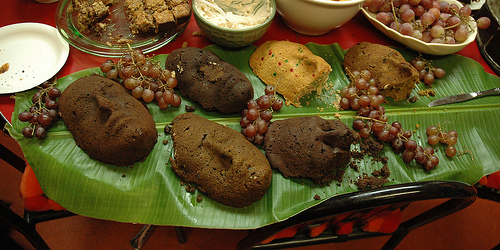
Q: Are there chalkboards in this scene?
A: No, there are no chalkboards.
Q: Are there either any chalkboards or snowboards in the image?
A: No, there are no chalkboards or snowboards.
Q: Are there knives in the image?
A: Yes, there is a knife.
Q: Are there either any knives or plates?
A: Yes, there is a knife.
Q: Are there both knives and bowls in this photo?
A: Yes, there are both a knife and a bowl.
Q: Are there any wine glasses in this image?
A: No, there are no wine glasses.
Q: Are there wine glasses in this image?
A: No, there are no wine glasses.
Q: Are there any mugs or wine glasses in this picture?
A: No, there are no wine glasses or mugs.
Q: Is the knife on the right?
A: Yes, the knife is on the right of the image.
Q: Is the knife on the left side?
A: No, the knife is on the right of the image.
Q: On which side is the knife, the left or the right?
A: The knife is on the right of the image.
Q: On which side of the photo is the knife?
A: The knife is on the right of the image.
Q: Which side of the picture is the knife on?
A: The knife is on the right of the image.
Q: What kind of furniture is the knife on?
A: The knife is on the table.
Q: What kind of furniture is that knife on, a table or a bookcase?
A: The knife is on a table.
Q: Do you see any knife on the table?
A: Yes, there is a knife on the table.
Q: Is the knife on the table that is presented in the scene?
A: Yes, the knife is on the table.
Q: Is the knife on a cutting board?
A: No, the knife is on the table.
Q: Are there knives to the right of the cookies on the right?
A: Yes, there is a knife to the right of the cookies.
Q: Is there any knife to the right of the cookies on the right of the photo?
A: Yes, there is a knife to the right of the cookies.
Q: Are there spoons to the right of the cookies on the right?
A: No, there is a knife to the right of the cookies.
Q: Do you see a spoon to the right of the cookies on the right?
A: No, there is a knife to the right of the cookies.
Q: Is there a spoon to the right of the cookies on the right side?
A: No, there is a knife to the right of the cookies.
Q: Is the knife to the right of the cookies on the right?
A: Yes, the knife is to the right of the cookies.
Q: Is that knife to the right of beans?
A: No, the knife is to the right of the cookies.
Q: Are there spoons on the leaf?
A: No, there is a knife on the leaf.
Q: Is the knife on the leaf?
A: Yes, the knife is on the leaf.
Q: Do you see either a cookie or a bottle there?
A: Yes, there are cookies.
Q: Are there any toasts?
A: No, there are no toasts.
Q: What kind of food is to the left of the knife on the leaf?
A: The food is cookies.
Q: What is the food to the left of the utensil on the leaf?
A: The food is cookies.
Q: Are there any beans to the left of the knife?
A: No, there are cookies to the left of the knife.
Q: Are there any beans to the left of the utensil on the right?
A: No, there are cookies to the left of the knife.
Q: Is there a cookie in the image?
A: Yes, there are cookies.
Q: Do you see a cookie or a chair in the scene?
A: Yes, there are cookies.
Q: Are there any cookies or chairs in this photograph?
A: Yes, there are cookies.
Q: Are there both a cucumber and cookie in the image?
A: No, there are cookies but no cucumbers.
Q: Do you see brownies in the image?
A: Yes, there are brownies.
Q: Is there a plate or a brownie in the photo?
A: Yes, there are brownies.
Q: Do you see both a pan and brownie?
A: No, there are brownies but no pans.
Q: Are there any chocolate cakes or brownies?
A: Yes, there are chocolate brownies.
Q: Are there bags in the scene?
A: No, there are no bags.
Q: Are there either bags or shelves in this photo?
A: No, there are no bags or shelves.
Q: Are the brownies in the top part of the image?
A: Yes, the brownies are in the top of the image.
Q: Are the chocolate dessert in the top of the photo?
A: Yes, the brownies are in the top of the image.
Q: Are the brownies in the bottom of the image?
A: No, the brownies are in the top of the image.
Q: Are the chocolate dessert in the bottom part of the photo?
A: No, the brownies are in the top of the image.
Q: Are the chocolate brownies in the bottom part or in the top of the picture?
A: The brownies are in the top of the image.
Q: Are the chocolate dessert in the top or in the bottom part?
A: The brownies are in the top of the image.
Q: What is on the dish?
A: The brownies are on the dish.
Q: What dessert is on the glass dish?
A: The dessert is brownies.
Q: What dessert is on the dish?
A: The dessert is brownies.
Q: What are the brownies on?
A: The brownies are on the dish.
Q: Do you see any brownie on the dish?
A: Yes, there are brownies on the dish.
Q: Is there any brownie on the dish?
A: Yes, there are brownies on the dish.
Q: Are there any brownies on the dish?
A: Yes, there are brownies on the dish.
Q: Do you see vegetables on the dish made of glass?
A: No, there are brownies on the dish.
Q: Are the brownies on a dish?
A: Yes, the brownies are on a dish.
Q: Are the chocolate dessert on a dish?
A: Yes, the brownies are on a dish.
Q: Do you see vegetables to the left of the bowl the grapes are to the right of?
A: No, there are brownies to the left of the bowl.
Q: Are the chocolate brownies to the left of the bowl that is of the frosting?
A: Yes, the brownies are to the left of the bowl.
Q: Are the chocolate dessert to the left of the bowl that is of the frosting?
A: Yes, the brownies are to the left of the bowl.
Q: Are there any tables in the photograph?
A: Yes, there is a table.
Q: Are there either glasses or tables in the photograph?
A: Yes, there is a table.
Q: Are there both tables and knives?
A: Yes, there are both a table and a knife.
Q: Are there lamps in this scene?
A: No, there are no lamps.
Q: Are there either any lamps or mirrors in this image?
A: No, there are no lamps or mirrors.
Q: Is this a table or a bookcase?
A: This is a table.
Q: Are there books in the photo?
A: No, there are no books.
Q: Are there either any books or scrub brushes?
A: No, there are no books or scrub brushes.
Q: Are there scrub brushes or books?
A: No, there are no books or scrub brushes.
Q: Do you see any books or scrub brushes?
A: No, there are no books or scrub brushes.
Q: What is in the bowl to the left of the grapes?
A: The frosting is in the bowl.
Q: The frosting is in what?
A: The frosting is in the bowl.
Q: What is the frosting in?
A: The frosting is in the bowl.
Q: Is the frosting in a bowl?
A: Yes, the frosting is in a bowl.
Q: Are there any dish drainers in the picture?
A: No, there are no dish drainers.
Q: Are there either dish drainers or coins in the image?
A: No, there are no dish drainers or coins.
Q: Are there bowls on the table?
A: Yes, there is a bowl on the table.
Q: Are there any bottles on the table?
A: No, there is a bowl on the table.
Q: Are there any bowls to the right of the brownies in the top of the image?
A: Yes, there is a bowl to the right of the brownies.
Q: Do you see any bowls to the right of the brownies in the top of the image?
A: Yes, there is a bowl to the right of the brownies.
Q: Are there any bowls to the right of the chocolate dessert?
A: Yes, there is a bowl to the right of the brownies.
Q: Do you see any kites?
A: No, there are no kites.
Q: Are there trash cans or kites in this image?
A: No, there are no kites or trash cans.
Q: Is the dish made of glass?
A: Yes, the dish is made of glass.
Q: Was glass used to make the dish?
A: Yes, the dish is made of glass.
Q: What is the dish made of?
A: The dish is made of glass.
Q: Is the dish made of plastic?
A: No, the dish is made of glass.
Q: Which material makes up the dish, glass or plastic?
A: The dish is made of glass.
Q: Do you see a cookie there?
A: Yes, there are cookies.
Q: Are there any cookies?
A: Yes, there are cookies.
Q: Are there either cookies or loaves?
A: Yes, there are cookies.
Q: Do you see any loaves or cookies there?
A: Yes, there are cookies.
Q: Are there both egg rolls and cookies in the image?
A: No, there are cookies but no egg rolls.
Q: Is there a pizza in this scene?
A: No, there are no pizzas.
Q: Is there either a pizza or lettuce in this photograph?
A: No, there are no pizzas or lettuce.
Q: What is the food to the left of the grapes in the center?
A: The food is cookies.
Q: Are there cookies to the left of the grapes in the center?
A: Yes, there are cookies to the left of the grapes.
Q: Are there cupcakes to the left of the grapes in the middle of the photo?
A: No, there are cookies to the left of the grapes.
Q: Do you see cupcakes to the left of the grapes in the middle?
A: No, there are cookies to the left of the grapes.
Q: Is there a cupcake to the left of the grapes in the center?
A: No, there are cookies to the left of the grapes.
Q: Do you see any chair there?
A: Yes, there is a chair.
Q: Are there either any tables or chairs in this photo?
A: Yes, there is a chair.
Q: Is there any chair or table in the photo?
A: Yes, there is a chair.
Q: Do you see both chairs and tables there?
A: Yes, there are both a chair and a table.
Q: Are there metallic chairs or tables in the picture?
A: Yes, there is a metal chair.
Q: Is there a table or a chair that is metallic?
A: Yes, the chair is metallic.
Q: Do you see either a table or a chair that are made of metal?
A: Yes, the chair is made of metal.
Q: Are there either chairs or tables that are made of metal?
A: Yes, the chair is made of metal.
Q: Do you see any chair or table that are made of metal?
A: Yes, the chair is made of metal.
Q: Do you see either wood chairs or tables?
A: Yes, there is a wood chair.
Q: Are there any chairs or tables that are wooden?
A: Yes, the chair is wooden.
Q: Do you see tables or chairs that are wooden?
A: Yes, the chair is wooden.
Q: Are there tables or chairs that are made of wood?
A: Yes, the chair is made of wood.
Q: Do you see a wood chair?
A: Yes, there is a wood chair.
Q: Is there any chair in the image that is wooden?
A: Yes, there is a wood chair.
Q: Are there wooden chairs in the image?
A: Yes, there is a wood chair.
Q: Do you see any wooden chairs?
A: Yes, there is a wood chair.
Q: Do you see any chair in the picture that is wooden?
A: Yes, there is a chair that is wooden.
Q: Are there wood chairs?
A: Yes, there is a chair that is made of wood.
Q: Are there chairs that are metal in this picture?
A: Yes, there is a metal chair.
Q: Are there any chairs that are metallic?
A: Yes, there is a chair that is metallic.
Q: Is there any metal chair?
A: Yes, there is a chair that is made of metal.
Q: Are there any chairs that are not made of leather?
A: Yes, there is a chair that is made of metal.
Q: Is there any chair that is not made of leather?
A: Yes, there is a chair that is made of metal.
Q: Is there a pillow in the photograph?
A: No, there are no pillows.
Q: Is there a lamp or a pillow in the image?
A: No, there are no pillows or lamps.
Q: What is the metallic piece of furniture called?
A: The piece of furniture is a chair.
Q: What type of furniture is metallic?
A: The furniture is a chair.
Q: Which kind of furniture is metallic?
A: The furniture is a chair.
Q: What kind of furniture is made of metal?
A: The furniture is a chair.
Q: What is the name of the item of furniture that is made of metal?
A: The piece of furniture is a chair.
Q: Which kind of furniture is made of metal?
A: The furniture is a chair.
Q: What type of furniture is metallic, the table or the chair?
A: The chair is metallic.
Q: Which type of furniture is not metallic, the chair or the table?
A: The table is not metallic.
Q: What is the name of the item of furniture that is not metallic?
A: The piece of furniture is a table.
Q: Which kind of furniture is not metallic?
A: The furniture is a table.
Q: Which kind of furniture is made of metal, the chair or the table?
A: The chair is made of metal.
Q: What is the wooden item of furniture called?
A: The piece of furniture is a chair.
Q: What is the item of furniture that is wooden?
A: The piece of furniture is a chair.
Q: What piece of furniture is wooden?
A: The piece of furniture is a chair.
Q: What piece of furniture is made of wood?
A: The piece of furniture is a chair.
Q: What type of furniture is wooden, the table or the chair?
A: The chair is wooden.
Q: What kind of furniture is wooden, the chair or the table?
A: The chair is wooden.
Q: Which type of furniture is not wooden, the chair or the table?
A: The table is not wooden.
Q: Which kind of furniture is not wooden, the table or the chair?
A: The table is not wooden.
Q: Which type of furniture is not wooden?
A: The furniture is a table.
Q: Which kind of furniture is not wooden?
A: The furniture is a table.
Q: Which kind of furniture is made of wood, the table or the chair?
A: The chair is made of wood.